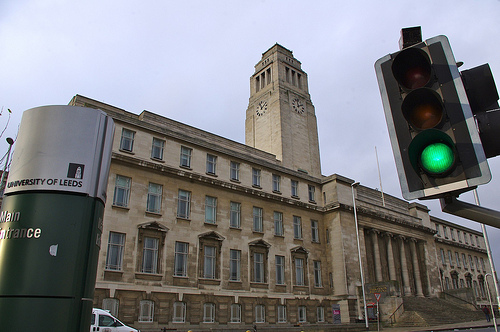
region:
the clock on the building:
[290, 95, 307, 115]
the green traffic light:
[416, 142, 455, 174]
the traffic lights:
[366, 19, 498, 210]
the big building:
[70, 41, 492, 330]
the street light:
[346, 180, 376, 330]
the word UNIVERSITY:
[5, 175, 46, 189]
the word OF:
[45, 175, 58, 185]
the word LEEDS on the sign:
[57, 175, 82, 190]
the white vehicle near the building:
[90, 302, 131, 327]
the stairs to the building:
[398, 288, 480, 329]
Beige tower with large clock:
[236, 32, 343, 160]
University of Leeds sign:
[2, 137, 106, 262]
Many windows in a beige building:
[103, 118, 337, 328]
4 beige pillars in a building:
[352, 219, 436, 306]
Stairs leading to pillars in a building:
[380, 225, 498, 322]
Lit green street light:
[375, 119, 492, 207]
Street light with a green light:
[346, 3, 478, 230]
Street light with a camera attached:
[339, 15, 498, 215]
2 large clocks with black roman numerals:
[246, 85, 317, 137]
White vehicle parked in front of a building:
[71, 295, 198, 330]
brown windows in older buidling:
[140, 212, 170, 289]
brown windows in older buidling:
[185, 229, 226, 290]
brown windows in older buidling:
[241, 227, 271, 295]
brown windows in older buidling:
[272, 230, 316, 291]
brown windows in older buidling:
[362, 230, 384, 294]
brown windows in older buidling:
[379, 237, 407, 299]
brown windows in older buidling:
[142, 177, 166, 217]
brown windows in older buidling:
[191, 174, 226, 231]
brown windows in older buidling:
[235, 190, 275, 255]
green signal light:
[408, 130, 443, 200]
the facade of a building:
[117, 129, 372, 330]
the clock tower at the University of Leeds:
[239, 37, 327, 189]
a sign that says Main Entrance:
[3, 102, 116, 322]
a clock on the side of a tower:
[290, 95, 309, 115]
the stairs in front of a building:
[365, 268, 495, 328]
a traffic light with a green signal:
[366, 33, 493, 209]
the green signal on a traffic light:
[402, 130, 463, 180]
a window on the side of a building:
[248, 238, 273, 293]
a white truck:
[86, 300, 146, 330]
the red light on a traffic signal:
[383, 50, 436, 94]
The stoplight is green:
[385, 36, 490, 198]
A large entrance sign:
[5, 107, 107, 331]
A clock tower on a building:
[244, 43, 326, 182]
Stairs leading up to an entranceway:
[371, 287, 483, 327]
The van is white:
[91, 305, 140, 330]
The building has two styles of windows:
[141, 174, 326, 296]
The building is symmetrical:
[188, 198, 493, 328]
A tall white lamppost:
[347, 180, 381, 328]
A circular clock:
[251, 98, 270, 118]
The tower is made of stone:
[291, 113, 313, 161]